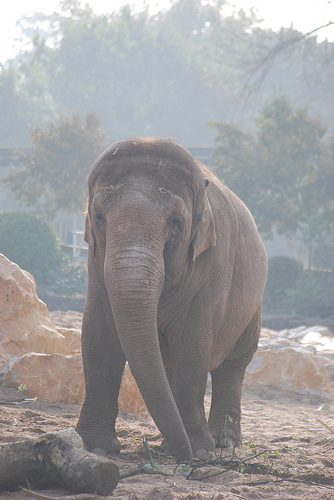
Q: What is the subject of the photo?
A: Animal.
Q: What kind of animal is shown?
A: Elephant.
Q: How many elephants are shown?
A: One.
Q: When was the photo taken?
A: Daytime.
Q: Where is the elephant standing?
A: In dirt.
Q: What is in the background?
A: Trees.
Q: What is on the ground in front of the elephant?
A: Log.